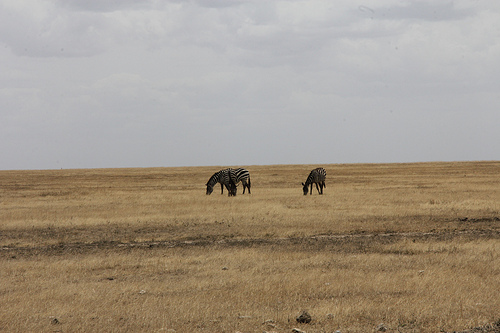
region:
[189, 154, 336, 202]
the zebras in the field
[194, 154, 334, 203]
the zebras grazing int he field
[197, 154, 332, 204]
the group of zebras gathered together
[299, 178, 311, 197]
the zebras eating off the ground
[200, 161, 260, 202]
the two zebrasgrazing of the grass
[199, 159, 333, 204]
the zebras in the barron ladscape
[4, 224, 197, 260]
the patch of dirt in the field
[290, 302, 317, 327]
the large rock in the field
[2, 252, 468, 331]
the brown grass in the field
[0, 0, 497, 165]
the cloudy sky above the zebras heads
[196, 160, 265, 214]
the zebra is eating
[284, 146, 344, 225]
the zebra is eating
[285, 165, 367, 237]
the zebra is eating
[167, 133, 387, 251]
the zebras in the field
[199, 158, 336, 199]
zebras in a field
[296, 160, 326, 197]
a zebra eating the grass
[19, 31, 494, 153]
clouds in the sky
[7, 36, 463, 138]
the grey sky behind the zebras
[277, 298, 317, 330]
rocks in the grass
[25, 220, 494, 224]
a path through the grass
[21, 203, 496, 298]
grass in front of the zebras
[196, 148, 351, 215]
zebras standing in a field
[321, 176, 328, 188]
the tail of the zebra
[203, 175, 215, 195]
the head of the zebra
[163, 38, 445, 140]
this is the sky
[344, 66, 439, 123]
the sky is blue in color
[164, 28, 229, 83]
this is the cloud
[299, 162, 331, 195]
this is a zebra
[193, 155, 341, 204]
the zebras are two in number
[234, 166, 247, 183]
the zebra is white and black in color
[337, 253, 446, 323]
this is a grass area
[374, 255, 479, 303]
the grass is dry in color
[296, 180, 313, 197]
the zebra is feeding on the grass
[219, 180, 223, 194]
this is the leg